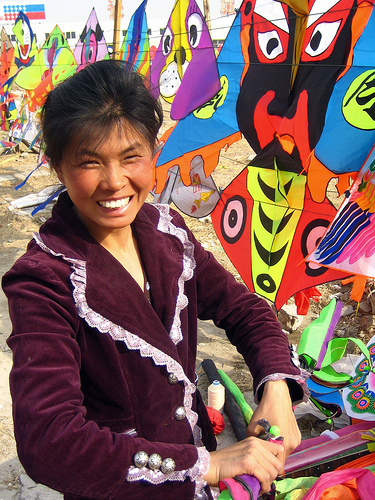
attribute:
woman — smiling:
[0, 58, 302, 500]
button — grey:
[136, 450, 147, 466]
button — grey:
[149, 452, 161, 470]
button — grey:
[163, 458, 175, 471]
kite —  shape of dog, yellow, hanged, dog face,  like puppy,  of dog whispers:
[149, 0, 223, 121]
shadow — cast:
[3, 458, 67, 499]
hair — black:
[37, 58, 163, 173]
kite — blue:
[116, 0, 152, 71]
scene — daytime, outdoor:
[0, 0, 374, 499]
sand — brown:
[2, 129, 64, 279]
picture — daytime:
[0, 3, 372, 498]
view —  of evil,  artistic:
[214, 3, 374, 313]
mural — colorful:
[215, 0, 374, 338]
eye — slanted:
[304, 20, 340, 56]